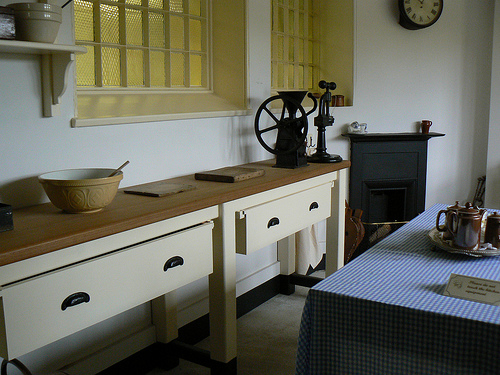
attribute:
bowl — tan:
[37, 167, 122, 214]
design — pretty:
[42, 186, 118, 204]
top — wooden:
[0, 156, 350, 266]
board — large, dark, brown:
[195, 167, 265, 181]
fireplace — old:
[349, 134, 431, 242]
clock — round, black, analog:
[392, 0, 444, 31]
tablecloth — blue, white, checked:
[298, 203, 499, 375]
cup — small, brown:
[422, 121, 431, 135]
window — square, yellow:
[72, 0, 210, 93]